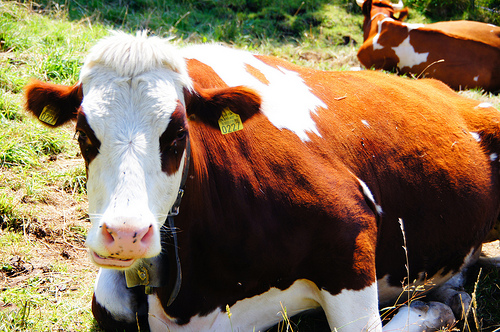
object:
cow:
[25, 33, 499, 330]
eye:
[75, 127, 95, 149]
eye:
[170, 133, 186, 151]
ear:
[183, 84, 263, 129]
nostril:
[141, 223, 157, 243]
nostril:
[101, 221, 116, 245]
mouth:
[87, 245, 142, 267]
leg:
[316, 267, 456, 331]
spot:
[360, 118, 370, 126]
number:
[222, 121, 241, 134]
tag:
[216, 106, 244, 136]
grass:
[42, 48, 62, 77]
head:
[24, 28, 264, 271]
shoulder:
[294, 170, 379, 294]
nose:
[100, 222, 154, 258]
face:
[75, 97, 189, 271]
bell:
[123, 249, 167, 294]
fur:
[84, 28, 189, 78]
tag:
[39, 105, 59, 127]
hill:
[1, 1, 500, 331]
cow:
[355, 0, 499, 94]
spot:
[349, 169, 384, 214]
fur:
[159, 98, 188, 177]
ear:
[25, 80, 84, 129]